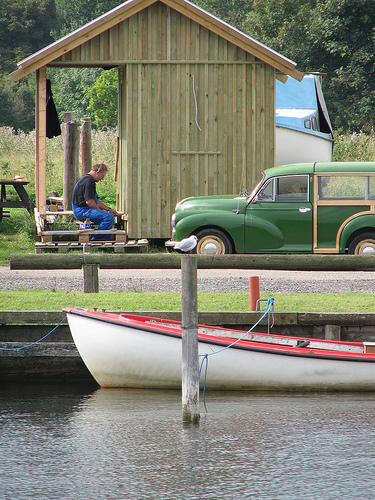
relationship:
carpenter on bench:
[71, 162, 120, 242] [30, 193, 127, 238]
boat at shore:
[61, 306, 375, 392] [5, 285, 352, 373]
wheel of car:
[350, 238, 373, 261] [164, 161, 375, 272]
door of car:
[246, 173, 311, 252] [164, 161, 375, 272]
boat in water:
[61, 306, 375, 392] [9, 424, 372, 491]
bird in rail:
[164, 234, 199, 257] [10, 254, 373, 271]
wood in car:
[312, 171, 374, 254] [164, 161, 375, 272]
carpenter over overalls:
[71, 162, 120, 242] [65, 172, 116, 235]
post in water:
[178, 250, 206, 426] [0, 365, 374, 496]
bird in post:
[166, 233, 204, 252] [178, 253, 201, 426]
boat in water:
[59, 305, 374, 411] [4, 383, 372, 497]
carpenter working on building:
[71, 162, 120, 242] [8, 0, 305, 254]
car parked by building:
[167, 161, 374, 255] [8, 0, 305, 254]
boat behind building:
[272, 66, 345, 166] [8, 0, 305, 254]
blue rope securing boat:
[199, 297, 275, 414] [61, 306, 375, 392]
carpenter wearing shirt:
[71, 162, 120, 242] [68, 172, 98, 208]